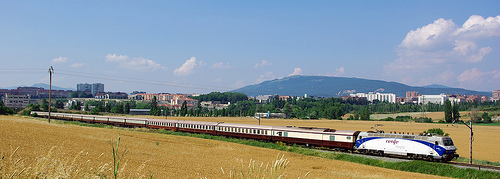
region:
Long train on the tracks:
[19, 104, 463, 158]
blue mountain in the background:
[226, 55, 437, 92]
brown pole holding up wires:
[39, 59, 58, 125]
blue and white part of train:
[357, 129, 459, 156]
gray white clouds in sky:
[397, 10, 498, 63]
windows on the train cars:
[148, 119, 275, 140]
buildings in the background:
[340, 79, 490, 108]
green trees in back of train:
[240, 100, 369, 115]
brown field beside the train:
[34, 132, 183, 173]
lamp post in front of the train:
[453, 118, 483, 165]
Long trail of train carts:
[26, 109, 461, 162]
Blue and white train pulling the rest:
[357, 129, 457, 164]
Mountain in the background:
[228, 70, 463, 97]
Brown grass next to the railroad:
[6, 140, 233, 177]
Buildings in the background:
[10, 86, 498, 113]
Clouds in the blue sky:
[385, 15, 497, 79]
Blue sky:
[2, 2, 392, 44]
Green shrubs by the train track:
[335, 151, 493, 177]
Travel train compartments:
[142, 115, 297, 149]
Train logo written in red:
[382, 137, 402, 144]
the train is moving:
[20, 84, 454, 163]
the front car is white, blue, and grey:
[344, 122, 465, 167]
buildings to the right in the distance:
[256, 76, 479, 118]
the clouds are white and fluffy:
[367, 10, 497, 77]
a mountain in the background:
[240, 54, 405, 95]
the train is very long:
[18, 80, 467, 158]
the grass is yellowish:
[38, 132, 294, 172]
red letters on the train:
[373, 131, 410, 152]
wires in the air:
[27, 57, 182, 86]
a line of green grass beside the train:
[150, 129, 432, 174]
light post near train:
[38, 60, 65, 128]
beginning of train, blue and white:
[352, 120, 458, 160]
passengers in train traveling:
[150, 115, 270, 131]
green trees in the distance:
[282, 95, 369, 115]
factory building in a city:
[345, 86, 395, 97]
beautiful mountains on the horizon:
[236, 80, 401, 96]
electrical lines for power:
[66, 65, 168, 95]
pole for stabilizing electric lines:
[41, 62, 56, 122]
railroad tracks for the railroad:
[460, 155, 495, 170]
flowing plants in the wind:
[17, 151, 88, 176]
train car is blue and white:
[354, 130, 472, 160]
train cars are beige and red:
[157, 116, 349, 155]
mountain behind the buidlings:
[250, 66, 435, 100]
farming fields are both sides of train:
[79, 108, 458, 174]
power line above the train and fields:
[22, 67, 310, 104]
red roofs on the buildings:
[144, 85, 210, 112]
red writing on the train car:
[378, 132, 411, 143]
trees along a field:
[299, 96, 468, 127]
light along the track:
[450, 115, 498, 169]